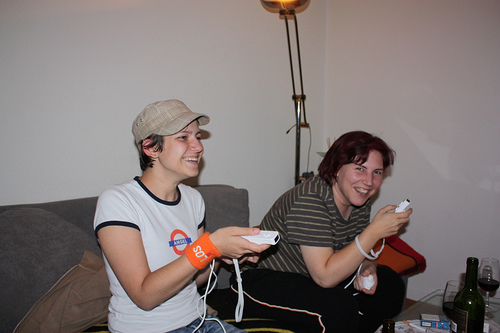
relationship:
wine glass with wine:
[477, 256, 499, 322] [479, 276, 499, 290]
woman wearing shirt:
[88, 98, 270, 332] [91, 177, 213, 333]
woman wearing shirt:
[232, 130, 414, 332] [249, 174, 372, 276]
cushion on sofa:
[3, 208, 106, 333] [0, 183, 249, 333]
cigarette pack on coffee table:
[418, 311, 453, 330] [375, 286, 500, 333]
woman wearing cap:
[88, 98, 270, 332] [127, 97, 212, 146]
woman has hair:
[232, 130, 414, 332] [316, 128, 397, 184]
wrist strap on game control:
[229, 255, 247, 324] [234, 224, 283, 252]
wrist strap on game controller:
[352, 233, 387, 259] [391, 193, 411, 218]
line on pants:
[229, 283, 330, 332] [227, 265, 409, 333]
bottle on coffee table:
[452, 253, 487, 333] [375, 286, 500, 333]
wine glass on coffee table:
[477, 256, 499, 322] [375, 286, 500, 333]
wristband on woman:
[184, 231, 220, 272] [88, 98, 270, 332]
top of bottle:
[465, 256, 481, 271] [452, 253, 487, 333]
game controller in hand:
[391, 193, 411, 218] [369, 203, 416, 238]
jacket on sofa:
[10, 248, 111, 332] [0, 183, 249, 333]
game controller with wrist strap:
[391, 193, 411, 218] [352, 233, 387, 259]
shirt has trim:
[91, 177, 213, 333] [129, 176, 181, 207]